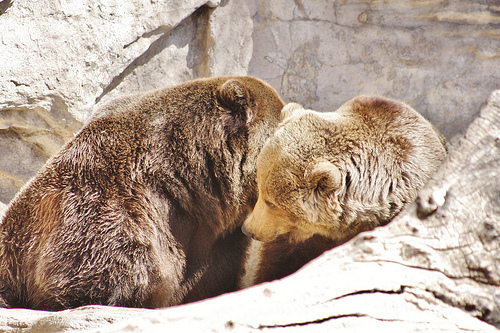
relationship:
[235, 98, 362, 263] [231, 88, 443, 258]
head of bear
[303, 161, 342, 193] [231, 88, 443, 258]
ear of bear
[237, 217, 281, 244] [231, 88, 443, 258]
nose of bear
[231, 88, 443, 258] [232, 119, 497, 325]
bear near tree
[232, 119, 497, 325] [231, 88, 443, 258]
tree in front of bear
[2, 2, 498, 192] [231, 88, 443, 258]
rock behind bear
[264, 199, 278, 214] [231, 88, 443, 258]
eye of bear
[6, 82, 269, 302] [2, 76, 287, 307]
skin of animal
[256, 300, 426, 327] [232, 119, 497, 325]
mark on tree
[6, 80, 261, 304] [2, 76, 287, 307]
fur on animal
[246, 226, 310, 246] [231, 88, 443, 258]
mouth on bear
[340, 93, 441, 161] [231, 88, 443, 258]
hump on bear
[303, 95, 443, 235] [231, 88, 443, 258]
fur on bear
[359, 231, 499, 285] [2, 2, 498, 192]
area on rock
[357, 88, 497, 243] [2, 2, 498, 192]
edge on rock